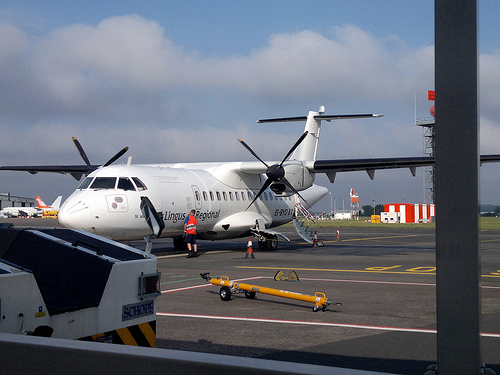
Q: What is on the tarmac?
A: The airplane.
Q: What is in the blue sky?
A: The clouds.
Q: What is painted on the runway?
A: A thin white line.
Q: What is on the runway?
A: A large aircraft.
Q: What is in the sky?
A: Clouds.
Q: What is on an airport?
A: A plane.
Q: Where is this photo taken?
A: At the airport.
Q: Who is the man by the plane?
A: A mechanic.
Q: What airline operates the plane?
A: AirLingus.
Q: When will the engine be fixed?
A: In one hour.